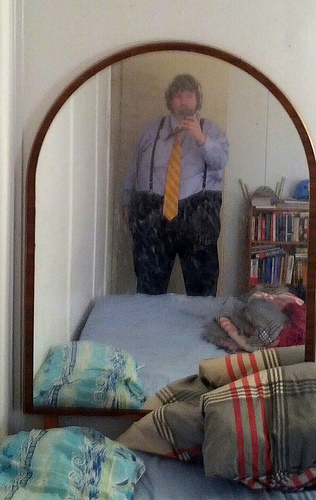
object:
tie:
[161, 123, 183, 221]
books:
[266, 214, 270, 241]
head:
[166, 72, 202, 116]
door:
[111, 51, 230, 297]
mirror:
[34, 49, 310, 411]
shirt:
[123, 112, 231, 207]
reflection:
[32, 342, 147, 410]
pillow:
[2, 424, 146, 498]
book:
[250, 257, 259, 284]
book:
[264, 256, 270, 282]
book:
[285, 254, 294, 286]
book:
[255, 247, 285, 259]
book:
[294, 260, 303, 284]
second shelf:
[251, 243, 315, 289]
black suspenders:
[149, 117, 166, 194]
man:
[123, 72, 229, 295]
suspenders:
[198, 116, 208, 194]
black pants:
[129, 189, 222, 295]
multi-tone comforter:
[199, 354, 315, 490]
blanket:
[113, 344, 316, 491]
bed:
[0, 425, 316, 500]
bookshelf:
[245, 202, 309, 291]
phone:
[184, 108, 193, 121]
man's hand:
[179, 115, 201, 140]